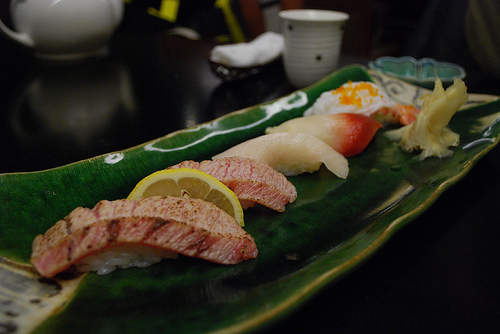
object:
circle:
[316, 55, 323, 61]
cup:
[278, 8, 351, 87]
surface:
[21, 70, 148, 136]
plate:
[0, 62, 498, 334]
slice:
[127, 168, 246, 228]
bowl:
[368, 55, 466, 90]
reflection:
[5, 55, 137, 146]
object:
[146, 0, 246, 43]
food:
[29, 82, 387, 278]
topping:
[331, 79, 387, 108]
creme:
[304, 80, 399, 117]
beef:
[30, 194, 260, 279]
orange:
[127, 168, 245, 228]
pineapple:
[212, 132, 349, 180]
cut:
[276, 8, 350, 90]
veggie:
[304, 180, 377, 243]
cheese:
[309, 81, 390, 117]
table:
[0, 21, 497, 331]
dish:
[0, 63, 499, 334]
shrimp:
[265, 112, 384, 158]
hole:
[315, 54, 323, 61]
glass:
[277, 8, 350, 88]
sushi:
[31, 75, 470, 278]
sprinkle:
[328, 80, 389, 107]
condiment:
[333, 80, 381, 105]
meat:
[164, 156, 297, 212]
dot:
[314, 55, 323, 62]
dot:
[287, 25, 295, 31]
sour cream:
[303, 80, 399, 117]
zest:
[333, 78, 380, 111]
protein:
[28, 195, 258, 279]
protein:
[164, 156, 296, 213]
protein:
[264, 112, 384, 156]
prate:
[0, 62, 497, 334]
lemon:
[126, 168, 245, 227]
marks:
[105, 217, 210, 258]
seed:
[182, 191, 190, 197]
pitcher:
[0, 1, 125, 60]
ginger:
[384, 76, 467, 159]